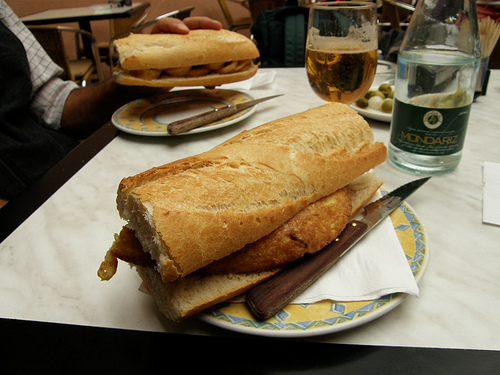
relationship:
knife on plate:
[161, 90, 286, 137] [89, 85, 266, 149]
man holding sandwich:
[0, 13, 124, 207] [104, 10, 266, 101]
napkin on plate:
[309, 222, 428, 328] [206, 194, 421, 356]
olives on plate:
[363, 82, 398, 122] [347, 86, 399, 130]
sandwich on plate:
[121, 99, 391, 276] [206, 194, 421, 356]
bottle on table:
[383, 4, 493, 177] [28, 50, 482, 372]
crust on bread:
[244, 133, 356, 199] [121, 99, 391, 276]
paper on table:
[0, 64, 495, 332] [28, 50, 482, 372]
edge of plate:
[326, 276, 418, 344] [206, 194, 421, 356]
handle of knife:
[239, 223, 376, 317] [223, 166, 433, 337]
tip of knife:
[405, 174, 430, 191] [223, 166, 433, 337]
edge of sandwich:
[113, 52, 157, 89] [104, 10, 266, 101]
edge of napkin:
[326, 276, 418, 344] [309, 222, 428, 328]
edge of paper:
[60, 156, 107, 205] [0, 64, 495, 332]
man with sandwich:
[0, 13, 124, 207] [104, 10, 266, 101]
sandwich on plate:
[104, 10, 266, 101] [89, 85, 266, 149]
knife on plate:
[223, 166, 433, 337] [206, 194, 421, 356]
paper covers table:
[0, 64, 495, 332] [28, 50, 482, 372]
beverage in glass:
[317, 37, 373, 93] [303, 0, 393, 105]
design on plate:
[226, 91, 246, 125] [89, 85, 266, 149]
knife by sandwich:
[161, 90, 286, 137] [104, 10, 266, 101]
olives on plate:
[363, 82, 398, 122] [89, 85, 266, 149]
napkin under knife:
[309, 222, 428, 328] [223, 166, 433, 337]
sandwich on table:
[121, 99, 391, 276] [28, 50, 482, 372]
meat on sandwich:
[261, 184, 362, 283] [121, 99, 391, 276]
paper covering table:
[0, 64, 495, 332] [22, 226, 80, 330]